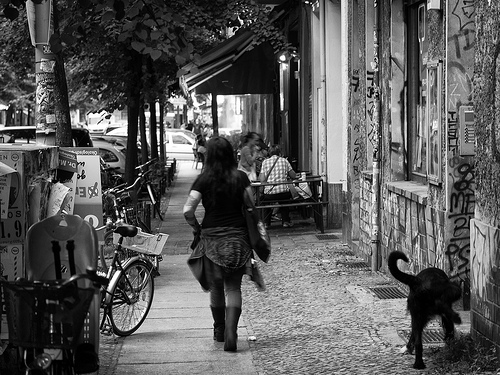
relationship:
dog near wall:
[381, 248, 468, 362] [303, 14, 480, 344]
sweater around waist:
[185, 230, 265, 292] [191, 194, 261, 239]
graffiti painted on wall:
[428, 7, 494, 309] [346, 7, 487, 353]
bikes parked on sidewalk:
[28, 222, 143, 327] [111, 148, 262, 372]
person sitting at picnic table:
[256, 143, 304, 235] [228, 165, 340, 228]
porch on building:
[163, 31, 328, 219] [181, 0, 347, 232]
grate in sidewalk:
[314, 229, 341, 243] [152, 184, 246, 374]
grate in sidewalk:
[336, 251, 368, 269] [152, 184, 246, 374]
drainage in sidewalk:
[369, 285, 407, 301] [152, 184, 246, 374]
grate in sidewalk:
[396, 319, 457, 347] [152, 184, 246, 374]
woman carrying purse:
[182, 137, 257, 351] [243, 196, 274, 263]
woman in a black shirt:
[182, 137, 257, 351] [183, 152, 265, 237]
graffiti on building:
[447, 3, 497, 308] [299, 4, 493, 295]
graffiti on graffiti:
[347, 54, 382, 174] [447, 3, 497, 308]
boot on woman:
[223, 302, 242, 350] [184, 136, 254, 351]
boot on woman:
[209, 306, 226, 342] [184, 136, 254, 351]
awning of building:
[175, 8, 280, 95] [273, 1, 497, 348]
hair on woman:
[200, 135, 243, 199] [182, 137, 257, 351]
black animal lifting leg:
[388, 250, 463, 369] [436, 282, 463, 327]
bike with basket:
[89, 214, 169, 336] [106, 208, 174, 258]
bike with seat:
[89, 214, 169, 336] [18, 210, 117, 357]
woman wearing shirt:
[256, 147, 300, 229] [252, 155, 298, 203]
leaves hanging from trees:
[115, 5, 195, 68] [0, 1, 265, 196]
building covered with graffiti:
[273, 1, 497, 348] [450, 160, 475, 279]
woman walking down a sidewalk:
[184, 136, 254, 351] [96, 158, 498, 374]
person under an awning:
[255, 150, 296, 229] [172, 3, 294, 98]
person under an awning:
[236, 129, 261, 183] [172, 3, 294, 98]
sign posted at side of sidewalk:
[46, 182, 77, 215] [33, 157, 497, 374]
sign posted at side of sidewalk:
[66, 148, 106, 247] [33, 157, 497, 374]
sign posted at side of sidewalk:
[2, 148, 28, 245] [33, 157, 497, 374]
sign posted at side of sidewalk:
[0, 162, 21, 219] [33, 157, 497, 374]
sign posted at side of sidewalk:
[57, 149, 78, 173] [33, 157, 497, 374]